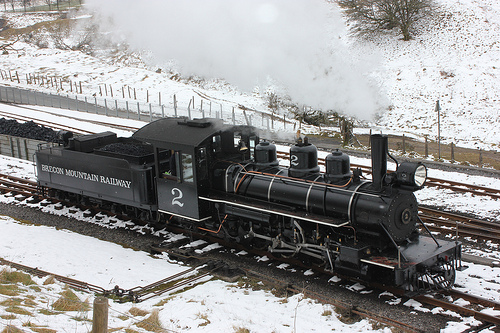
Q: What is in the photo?
A: Locomotive.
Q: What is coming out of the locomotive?
A: Steam.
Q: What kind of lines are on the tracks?
A: Fencing.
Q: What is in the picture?
A: Locomotives.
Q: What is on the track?
A: Train.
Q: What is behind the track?
A: Snow.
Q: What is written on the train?
A: 2.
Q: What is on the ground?
A: Snow.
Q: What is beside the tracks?
A: Snow.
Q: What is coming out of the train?
A: Steam.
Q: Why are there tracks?
A: For the train.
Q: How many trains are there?
A: One.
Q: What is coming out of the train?
A: Steam.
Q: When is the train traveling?
A: Daytime.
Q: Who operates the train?
A: Engineer.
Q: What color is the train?
A: Black.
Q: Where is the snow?
A: On the ground.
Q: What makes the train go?
A: Engine.